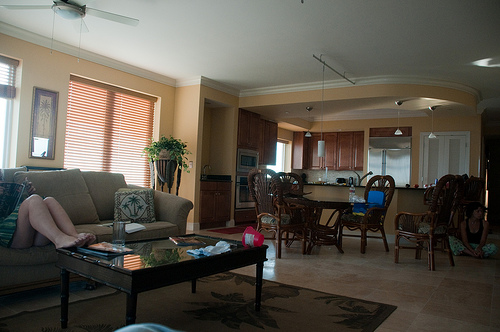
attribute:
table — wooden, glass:
[53, 231, 268, 331]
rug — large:
[0, 268, 399, 330]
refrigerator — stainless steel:
[366, 134, 411, 188]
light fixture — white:
[314, 55, 329, 161]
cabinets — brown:
[194, 177, 234, 232]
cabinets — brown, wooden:
[289, 127, 367, 174]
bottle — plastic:
[341, 173, 371, 210]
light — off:
[301, 129, 313, 138]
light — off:
[393, 127, 402, 136]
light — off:
[425, 131, 436, 140]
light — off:
[315, 139, 324, 158]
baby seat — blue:
[353, 190, 383, 214]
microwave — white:
[235, 145, 259, 174]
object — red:
[239, 222, 263, 249]